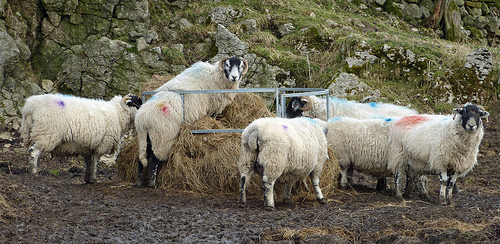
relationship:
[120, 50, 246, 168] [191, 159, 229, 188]
sheep on hay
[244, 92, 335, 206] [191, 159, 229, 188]
sheep eating hay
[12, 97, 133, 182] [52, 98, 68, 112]
sheep has dot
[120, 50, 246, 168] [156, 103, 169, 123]
sheep has dot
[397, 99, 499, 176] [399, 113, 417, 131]
sheep has dot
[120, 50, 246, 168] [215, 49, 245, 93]
sheep has face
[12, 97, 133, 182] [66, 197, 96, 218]
sheep of dirt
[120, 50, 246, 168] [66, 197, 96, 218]
sheep of dirt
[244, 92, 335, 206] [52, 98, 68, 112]
sheep of dot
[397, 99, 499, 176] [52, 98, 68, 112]
sheep of dot